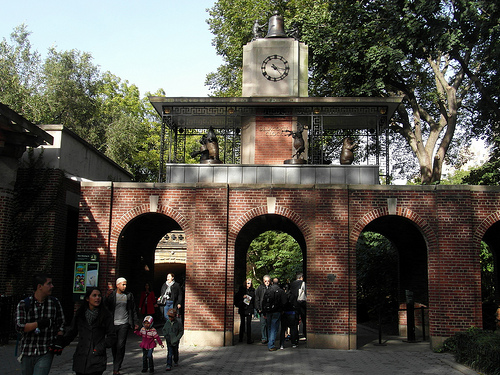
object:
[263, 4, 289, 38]
bell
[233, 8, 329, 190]
monument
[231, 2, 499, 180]
trees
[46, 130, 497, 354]
wall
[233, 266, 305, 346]
people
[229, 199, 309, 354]
archway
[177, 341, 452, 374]
path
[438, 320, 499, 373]
bushes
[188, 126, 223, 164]
animal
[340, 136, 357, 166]
statue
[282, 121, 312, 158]
horse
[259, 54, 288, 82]
clock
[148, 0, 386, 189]
building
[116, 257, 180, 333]
people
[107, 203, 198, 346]
archway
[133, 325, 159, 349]
coat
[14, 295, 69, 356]
shirt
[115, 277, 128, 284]
hat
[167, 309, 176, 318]
cap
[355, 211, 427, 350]
archway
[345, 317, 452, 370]
sidewalk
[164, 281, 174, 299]
cardigan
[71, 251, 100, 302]
sign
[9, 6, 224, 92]
sky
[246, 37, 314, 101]
stone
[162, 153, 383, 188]
platform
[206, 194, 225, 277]
brick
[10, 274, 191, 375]
people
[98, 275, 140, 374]
adults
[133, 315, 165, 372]
children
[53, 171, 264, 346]
structure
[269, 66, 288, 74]
hands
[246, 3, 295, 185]
tower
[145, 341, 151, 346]
pink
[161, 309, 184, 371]
boy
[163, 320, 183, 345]
sweatshirt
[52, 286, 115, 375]
woman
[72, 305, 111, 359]
coat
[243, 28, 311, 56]
top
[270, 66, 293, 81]
time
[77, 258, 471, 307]
row